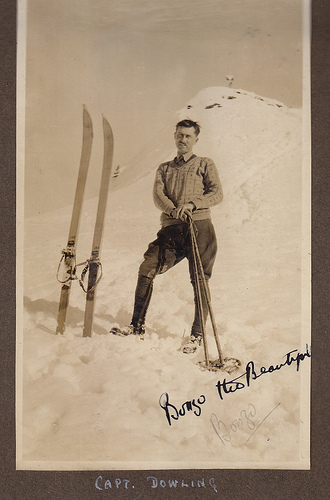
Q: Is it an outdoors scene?
A: Yes, it is outdoors.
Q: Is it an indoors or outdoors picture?
A: It is outdoors.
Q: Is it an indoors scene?
A: No, it is outdoors.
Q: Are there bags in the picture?
A: No, there are no bags.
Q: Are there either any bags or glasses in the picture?
A: No, there are no bags or glasses.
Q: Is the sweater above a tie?
A: Yes, the sweater is above a tie.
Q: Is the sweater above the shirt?
A: Yes, the sweater is above the shirt.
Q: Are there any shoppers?
A: No, there are no shoppers.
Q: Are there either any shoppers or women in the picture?
A: No, there are no shoppers or women.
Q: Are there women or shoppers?
A: No, there are no shoppers or women.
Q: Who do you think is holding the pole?
A: The man is holding the pole.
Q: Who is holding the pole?
A: The man is holding the pole.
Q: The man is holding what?
A: The man is holding the pole.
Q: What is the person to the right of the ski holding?
A: The man is holding the pole.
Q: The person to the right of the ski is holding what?
A: The man is holding the pole.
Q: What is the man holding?
A: The man is holding the pole.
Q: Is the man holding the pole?
A: Yes, the man is holding the pole.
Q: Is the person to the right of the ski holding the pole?
A: Yes, the man is holding the pole.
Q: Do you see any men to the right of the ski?
A: Yes, there is a man to the right of the ski.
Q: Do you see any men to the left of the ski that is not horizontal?
A: No, the man is to the right of the ski.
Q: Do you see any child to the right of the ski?
A: No, there is a man to the right of the ski.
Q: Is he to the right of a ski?
A: Yes, the man is to the right of a ski.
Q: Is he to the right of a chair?
A: No, the man is to the right of a ski.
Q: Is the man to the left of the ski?
A: No, the man is to the right of the ski.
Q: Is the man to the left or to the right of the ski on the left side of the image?
A: The man is to the right of the ski.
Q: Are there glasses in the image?
A: No, there are no glasses.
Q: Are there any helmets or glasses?
A: No, there are no glasses or helmets.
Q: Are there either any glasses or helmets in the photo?
A: No, there are no glasses or helmets.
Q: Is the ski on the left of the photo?
A: Yes, the ski is on the left of the image.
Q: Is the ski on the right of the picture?
A: No, the ski is on the left of the image.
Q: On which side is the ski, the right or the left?
A: The ski is on the left of the image.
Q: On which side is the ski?
A: The ski is on the left of the image.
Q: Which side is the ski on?
A: The ski is on the left of the image.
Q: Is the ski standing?
A: Yes, the ski is standing.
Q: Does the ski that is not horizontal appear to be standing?
A: Yes, the ski is standing.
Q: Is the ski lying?
A: No, the ski is standing.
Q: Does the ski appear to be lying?
A: No, the ski is standing.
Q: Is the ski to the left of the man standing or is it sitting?
A: The ski is standing.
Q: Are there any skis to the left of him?
A: Yes, there is a ski to the left of the man.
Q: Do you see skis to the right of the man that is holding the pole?
A: No, the ski is to the left of the man.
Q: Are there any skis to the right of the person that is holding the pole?
A: No, the ski is to the left of the man.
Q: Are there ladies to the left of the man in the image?
A: No, there is a ski to the left of the man.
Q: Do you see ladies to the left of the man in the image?
A: No, there is a ski to the left of the man.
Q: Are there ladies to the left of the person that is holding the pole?
A: No, there is a ski to the left of the man.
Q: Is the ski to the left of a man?
A: Yes, the ski is to the left of a man.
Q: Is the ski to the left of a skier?
A: No, the ski is to the left of a man.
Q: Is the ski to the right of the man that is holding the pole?
A: No, the ski is to the left of the man.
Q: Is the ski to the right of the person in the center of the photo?
A: No, the ski is to the left of the man.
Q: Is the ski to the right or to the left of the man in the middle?
A: The ski is to the left of the man.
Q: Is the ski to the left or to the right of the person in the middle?
A: The ski is to the left of the man.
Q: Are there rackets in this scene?
A: No, there are no rackets.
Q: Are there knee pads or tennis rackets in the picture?
A: No, there are no tennis rackets or knee pads.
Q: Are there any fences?
A: No, there are no fences.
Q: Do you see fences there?
A: No, there are no fences.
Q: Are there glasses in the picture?
A: No, there are no glasses.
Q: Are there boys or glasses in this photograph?
A: No, there are no glasses or boys.